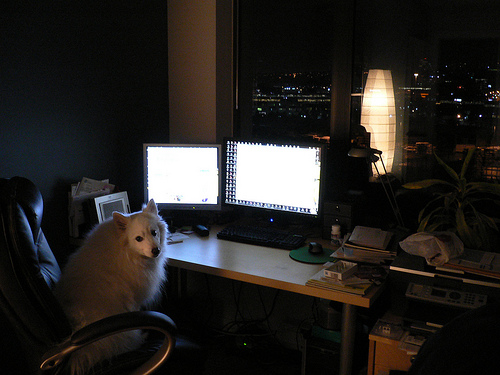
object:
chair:
[62, 198, 167, 368]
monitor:
[147, 146, 220, 205]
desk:
[55, 198, 168, 373]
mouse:
[308, 241, 322, 254]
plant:
[401, 155, 500, 251]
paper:
[72, 176, 115, 200]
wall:
[1, 1, 165, 228]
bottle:
[331, 225, 342, 247]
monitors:
[225, 140, 322, 215]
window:
[231, 2, 498, 217]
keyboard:
[217, 223, 306, 249]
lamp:
[361, 69, 398, 177]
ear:
[113, 211, 130, 232]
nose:
[151, 246, 160, 254]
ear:
[143, 199, 158, 215]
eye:
[135, 235, 144, 242]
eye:
[151, 230, 157, 237]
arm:
[39, 310, 182, 375]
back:
[3, 177, 61, 375]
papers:
[93, 191, 129, 224]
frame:
[24, 282, 391, 375]